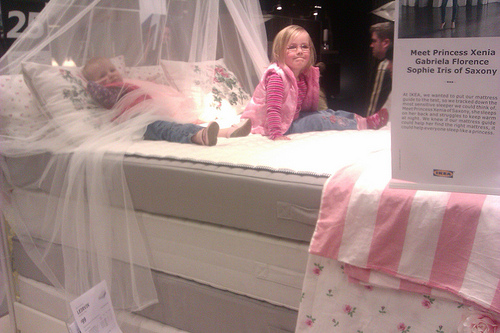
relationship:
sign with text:
[373, 2, 484, 195] [420, 50, 483, 71]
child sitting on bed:
[240, 25, 390, 141] [208, 142, 335, 163]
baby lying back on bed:
[81, 56, 252, 146] [244, 138, 285, 165]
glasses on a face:
[285, 42, 309, 51] [283, 31, 313, 66]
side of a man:
[361, 18, 393, 118] [362, 21, 395, 117]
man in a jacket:
[362, 21, 395, 117] [367, 56, 394, 110]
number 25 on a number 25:
[5, 8, 43, 41] [155, 122, 193, 151]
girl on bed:
[238, 20, 390, 134] [1, 48, 474, 206]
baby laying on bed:
[81, 56, 252, 146] [1, 29, 469, 198]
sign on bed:
[388, 33, 482, 190] [1, 48, 474, 206]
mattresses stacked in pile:
[0, 146, 330, 244] [10, 141, 437, 325]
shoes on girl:
[367, 104, 390, 134] [238, 20, 390, 134]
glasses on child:
[285, 44, 309, 51] [240, 25, 390, 141]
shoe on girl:
[220, 111, 253, 139] [81, 48, 254, 147]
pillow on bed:
[157, 52, 263, 120] [5, 39, 485, 259]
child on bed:
[240, 19, 389, 134] [5, 34, 481, 314]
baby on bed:
[81, 56, 252, 146] [5, 34, 481, 314]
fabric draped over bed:
[5, 3, 275, 322] [4, 51, 474, 327]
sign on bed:
[386, 3, 485, 183] [8, 5, 481, 323]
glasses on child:
[285, 44, 309, 51] [246, 19, 390, 143]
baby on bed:
[80, 51, 251, 150] [4, 51, 474, 327]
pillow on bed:
[159, 50, 254, 122] [4, 51, 474, 327]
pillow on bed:
[19, 47, 149, 139] [4, 51, 474, 327]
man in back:
[363, 15, 399, 112] [311, 8, 387, 106]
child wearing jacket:
[240, 19, 389, 134] [240, 58, 330, 138]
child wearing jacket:
[240, 19, 389, 134] [247, 62, 325, 132]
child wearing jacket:
[252, 24, 390, 134] [240, 58, 330, 138]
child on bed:
[240, 25, 390, 141] [16, 132, 485, 320]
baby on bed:
[80, 51, 251, 150] [8, 144, 413, 307]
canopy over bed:
[2, 3, 265, 148] [29, 154, 413, 326]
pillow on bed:
[166, 52, 255, 119] [15, 69, 368, 326]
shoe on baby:
[201, 121, 222, 147] [81, 56, 252, 146]